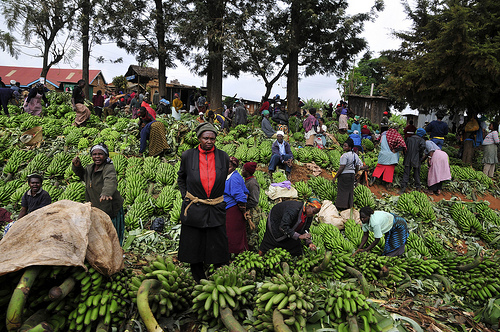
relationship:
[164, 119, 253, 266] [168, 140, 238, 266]
woman wearing jacket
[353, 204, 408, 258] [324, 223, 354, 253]
woman kneeling by bananas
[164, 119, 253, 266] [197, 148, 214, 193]
woman wearing red shirt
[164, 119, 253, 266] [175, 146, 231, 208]
woman wearing black jacket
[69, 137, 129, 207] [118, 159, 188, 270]
lady standing in front of bananas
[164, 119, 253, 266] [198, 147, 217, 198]
woman wearing shirt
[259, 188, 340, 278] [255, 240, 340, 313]
lady reaches for banana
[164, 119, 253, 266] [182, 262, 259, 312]
woman stands near bananas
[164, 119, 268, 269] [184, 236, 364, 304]
woman in front of bananas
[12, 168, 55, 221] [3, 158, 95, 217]
smiling man in front of bananas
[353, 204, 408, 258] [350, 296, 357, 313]
woman orginizing banana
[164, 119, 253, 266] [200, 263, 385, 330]
woman standing next to bananas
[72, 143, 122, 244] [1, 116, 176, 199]
woman in front of bananas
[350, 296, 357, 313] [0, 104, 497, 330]
banana on ground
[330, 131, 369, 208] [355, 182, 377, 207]
woman near bananas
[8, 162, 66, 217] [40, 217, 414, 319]
boy standing in front of banana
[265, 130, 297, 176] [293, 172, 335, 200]
man front of bananas